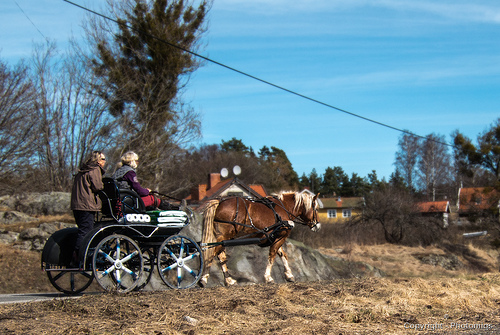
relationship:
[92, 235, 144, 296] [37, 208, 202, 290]
wheel of cart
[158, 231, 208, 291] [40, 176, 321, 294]
wheel of cart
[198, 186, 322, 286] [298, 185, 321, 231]
horse has face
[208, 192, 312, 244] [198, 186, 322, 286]
threads tied to horse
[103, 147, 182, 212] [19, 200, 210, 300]
person sitting in car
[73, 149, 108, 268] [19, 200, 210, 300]
people sitting in car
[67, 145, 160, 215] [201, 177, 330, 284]
two people driving horse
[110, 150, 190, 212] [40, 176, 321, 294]
person standing in cart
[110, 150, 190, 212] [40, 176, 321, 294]
person in cart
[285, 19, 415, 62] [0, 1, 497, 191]
clouds in sky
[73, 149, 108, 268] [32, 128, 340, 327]
people riding in buggy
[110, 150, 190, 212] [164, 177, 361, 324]
person pulled by horse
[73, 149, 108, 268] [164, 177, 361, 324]
people pulled by horse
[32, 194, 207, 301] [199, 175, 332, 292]
cart pulled by horse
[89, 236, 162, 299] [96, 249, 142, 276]
wheel with spokes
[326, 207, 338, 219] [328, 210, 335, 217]
window with four panes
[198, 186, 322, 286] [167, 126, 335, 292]
horse iron stand to hold horse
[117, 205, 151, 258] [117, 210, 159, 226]
package of toilet paper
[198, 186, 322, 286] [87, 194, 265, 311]
horse walking very slowly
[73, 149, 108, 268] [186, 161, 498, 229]
people are going to town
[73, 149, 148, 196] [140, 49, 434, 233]
people are enjoying sunshine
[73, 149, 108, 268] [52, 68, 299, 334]
people are out in day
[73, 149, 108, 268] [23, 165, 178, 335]
people are enjoying their day